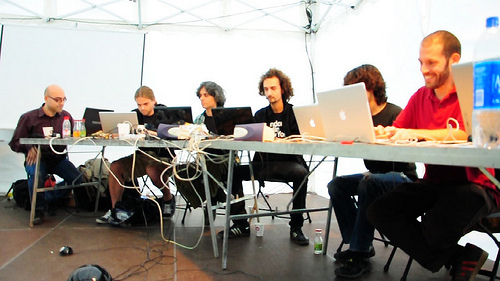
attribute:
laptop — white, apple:
[316, 82, 418, 147]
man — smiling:
[364, 30, 499, 281]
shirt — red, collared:
[387, 83, 498, 194]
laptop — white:
[290, 101, 337, 145]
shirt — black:
[252, 101, 314, 176]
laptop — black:
[210, 107, 256, 141]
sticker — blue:
[472, 59, 500, 110]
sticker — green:
[82, 128, 88, 140]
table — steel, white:
[18, 131, 499, 270]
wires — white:
[46, 130, 208, 178]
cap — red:
[64, 115, 71, 121]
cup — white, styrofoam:
[41, 124, 55, 139]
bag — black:
[2, 178, 55, 212]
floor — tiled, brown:
[1, 189, 500, 280]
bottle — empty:
[313, 228, 326, 256]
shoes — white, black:
[215, 214, 312, 245]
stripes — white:
[230, 227, 247, 237]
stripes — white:
[290, 231, 300, 240]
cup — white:
[254, 221, 266, 238]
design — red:
[256, 226, 262, 231]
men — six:
[10, 28, 492, 138]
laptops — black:
[80, 99, 261, 140]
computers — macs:
[290, 80, 422, 150]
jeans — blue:
[327, 168, 413, 252]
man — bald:
[7, 83, 94, 225]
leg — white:
[215, 151, 241, 275]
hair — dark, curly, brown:
[257, 66, 296, 102]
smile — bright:
[421, 71, 440, 86]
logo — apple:
[337, 105, 350, 124]